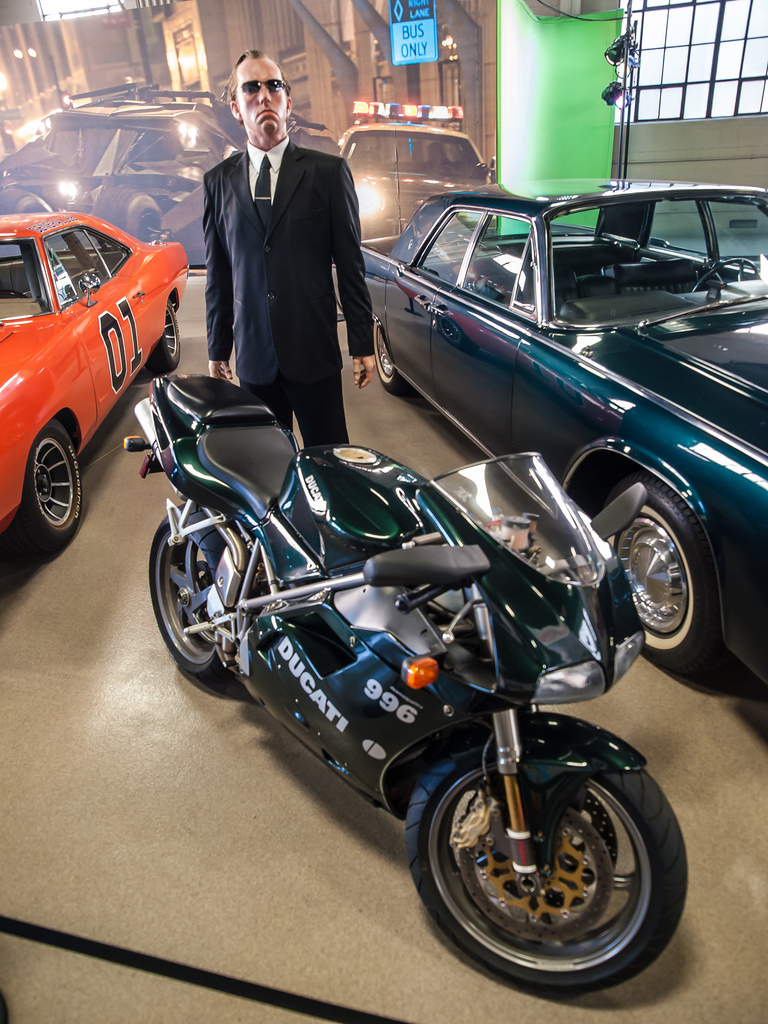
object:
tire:
[415, 716, 697, 1002]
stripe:
[516, 835, 531, 870]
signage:
[389, 0, 437, 68]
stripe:
[2, 914, 398, 1021]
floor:
[2, 275, 765, 1021]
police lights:
[347, 98, 464, 123]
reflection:
[385, 275, 519, 373]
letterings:
[64, 444, 83, 520]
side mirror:
[83, 269, 103, 305]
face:
[232, 50, 292, 144]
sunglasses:
[234, 79, 288, 95]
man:
[198, 49, 375, 449]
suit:
[201, 143, 372, 445]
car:
[354, 181, 765, 684]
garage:
[0, 0, 763, 1019]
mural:
[0, 0, 495, 267]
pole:
[619, 6, 632, 177]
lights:
[600, 28, 641, 107]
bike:
[122, 378, 689, 996]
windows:
[617, 0, 766, 124]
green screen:
[501, 2, 612, 230]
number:
[97, 299, 144, 389]